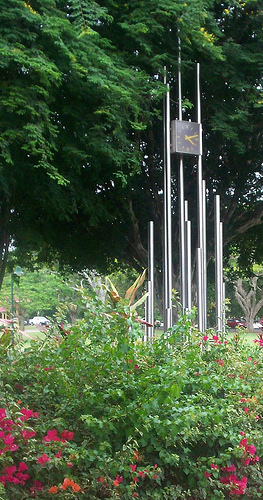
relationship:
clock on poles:
[145, 118, 229, 157] [133, 82, 253, 309]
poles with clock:
[133, 82, 253, 309] [145, 118, 229, 157]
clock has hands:
[145, 118, 229, 157] [175, 133, 201, 155]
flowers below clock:
[1, 405, 76, 488] [145, 118, 229, 157]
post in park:
[0, 263, 51, 311] [7, 239, 173, 343]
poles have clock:
[133, 82, 253, 309] [145, 118, 229, 157]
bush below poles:
[76, 321, 233, 458] [133, 82, 253, 309]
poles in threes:
[133, 82, 253, 309] [166, 218, 205, 306]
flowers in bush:
[1, 405, 76, 488] [76, 321, 233, 458]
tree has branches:
[19, 31, 170, 226] [25, 145, 138, 209]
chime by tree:
[119, 185, 256, 318] [19, 31, 170, 226]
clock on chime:
[145, 118, 229, 157] [119, 185, 256, 318]